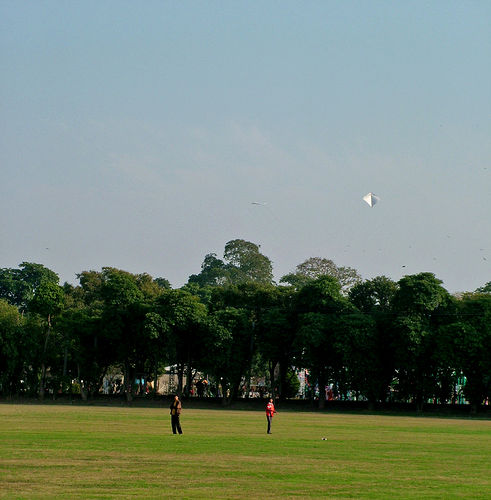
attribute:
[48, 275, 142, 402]
tree — along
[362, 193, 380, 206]
kite — white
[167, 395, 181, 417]
jacket — brown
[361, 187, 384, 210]
kite — white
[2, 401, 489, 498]
grass — green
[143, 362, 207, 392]
buildings — white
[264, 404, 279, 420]
shirt — red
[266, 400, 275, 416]
shirt — red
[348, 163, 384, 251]
kite — white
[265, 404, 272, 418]
shirt — red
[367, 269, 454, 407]
tree — along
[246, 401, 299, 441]
jacket — red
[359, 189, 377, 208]
kite — white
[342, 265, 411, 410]
tree — along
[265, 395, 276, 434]
person — standing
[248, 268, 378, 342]
tree — along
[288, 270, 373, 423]
tree — along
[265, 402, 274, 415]
shirt — red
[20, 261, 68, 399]
tree — along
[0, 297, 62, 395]
tree — along side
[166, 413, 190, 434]
pants — black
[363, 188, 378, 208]
kite — white, diamond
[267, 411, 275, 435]
jeans — blue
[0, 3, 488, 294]
sky — clear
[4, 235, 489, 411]
trees — distant